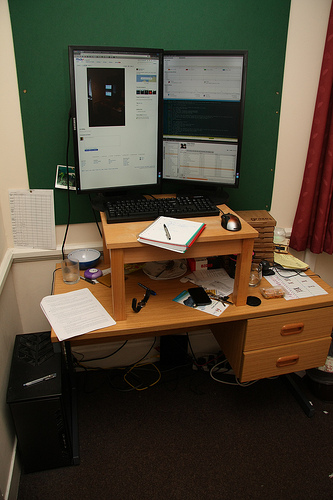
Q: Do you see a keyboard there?
A: Yes, there is a keyboard.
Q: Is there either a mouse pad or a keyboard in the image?
A: Yes, there is a keyboard.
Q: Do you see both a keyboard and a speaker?
A: No, there is a keyboard but no speakers.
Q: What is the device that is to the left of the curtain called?
A: The device is a keyboard.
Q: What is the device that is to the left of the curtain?
A: The device is a keyboard.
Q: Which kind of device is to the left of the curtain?
A: The device is a keyboard.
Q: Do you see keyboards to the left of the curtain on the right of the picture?
A: Yes, there is a keyboard to the left of the curtain.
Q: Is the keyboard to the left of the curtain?
A: Yes, the keyboard is to the left of the curtain.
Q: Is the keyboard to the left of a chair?
A: No, the keyboard is to the left of the curtain.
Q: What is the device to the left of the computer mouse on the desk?
A: The device is a keyboard.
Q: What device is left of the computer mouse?
A: The device is a keyboard.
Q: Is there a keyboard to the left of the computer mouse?
A: Yes, there is a keyboard to the left of the computer mouse.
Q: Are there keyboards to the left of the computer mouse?
A: Yes, there is a keyboard to the left of the computer mouse.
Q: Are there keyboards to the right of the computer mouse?
A: No, the keyboard is to the left of the computer mouse.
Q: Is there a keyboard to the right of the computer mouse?
A: No, the keyboard is to the left of the computer mouse.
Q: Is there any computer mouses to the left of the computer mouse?
A: No, there is a keyboard to the left of the computer mouse.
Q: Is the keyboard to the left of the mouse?
A: Yes, the keyboard is to the left of the mouse.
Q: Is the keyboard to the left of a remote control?
A: No, the keyboard is to the left of the mouse.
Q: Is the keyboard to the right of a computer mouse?
A: No, the keyboard is to the left of a computer mouse.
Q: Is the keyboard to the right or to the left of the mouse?
A: The keyboard is to the left of the mouse.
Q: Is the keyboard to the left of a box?
A: Yes, the keyboard is to the left of a box.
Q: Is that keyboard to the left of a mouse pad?
A: No, the keyboard is to the left of a box.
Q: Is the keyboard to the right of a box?
A: No, the keyboard is to the left of a box.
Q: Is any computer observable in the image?
A: Yes, there is a computer.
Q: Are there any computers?
A: Yes, there is a computer.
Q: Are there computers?
A: Yes, there is a computer.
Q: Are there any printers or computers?
A: Yes, there is a computer.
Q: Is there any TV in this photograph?
A: No, there are no televisions.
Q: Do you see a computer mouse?
A: Yes, there is a computer mouse.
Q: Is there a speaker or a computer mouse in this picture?
A: Yes, there is a computer mouse.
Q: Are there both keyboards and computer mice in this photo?
A: Yes, there are both a computer mouse and a keyboard.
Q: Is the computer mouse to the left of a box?
A: Yes, the computer mouse is to the left of a box.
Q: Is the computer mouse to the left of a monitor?
A: No, the computer mouse is to the left of a box.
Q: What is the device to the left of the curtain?
A: The device is a computer mouse.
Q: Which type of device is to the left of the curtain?
A: The device is a computer mouse.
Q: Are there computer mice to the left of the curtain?
A: Yes, there is a computer mouse to the left of the curtain.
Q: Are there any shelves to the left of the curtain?
A: No, there is a computer mouse to the left of the curtain.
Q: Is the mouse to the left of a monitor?
A: No, the mouse is to the left of the curtain.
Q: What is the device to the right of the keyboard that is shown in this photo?
A: The device is a computer mouse.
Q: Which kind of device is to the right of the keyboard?
A: The device is a computer mouse.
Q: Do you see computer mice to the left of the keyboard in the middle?
A: No, the computer mouse is to the right of the keyboard.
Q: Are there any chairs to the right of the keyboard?
A: No, there is a computer mouse to the right of the keyboard.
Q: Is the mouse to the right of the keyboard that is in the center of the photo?
A: Yes, the mouse is to the right of the keyboard.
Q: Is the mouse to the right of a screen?
A: No, the mouse is to the right of the keyboard.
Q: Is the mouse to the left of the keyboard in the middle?
A: No, the mouse is to the right of the keyboard.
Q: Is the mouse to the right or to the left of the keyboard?
A: The mouse is to the right of the keyboard.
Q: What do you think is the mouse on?
A: The mouse is on the desk.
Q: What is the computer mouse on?
A: The mouse is on the desk.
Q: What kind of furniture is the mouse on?
A: The mouse is on the desk.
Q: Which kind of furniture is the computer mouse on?
A: The mouse is on the desk.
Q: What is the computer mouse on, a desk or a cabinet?
A: The computer mouse is on a desk.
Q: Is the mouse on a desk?
A: Yes, the mouse is on a desk.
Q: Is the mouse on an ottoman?
A: No, the mouse is on a desk.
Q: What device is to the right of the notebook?
A: The device is a computer mouse.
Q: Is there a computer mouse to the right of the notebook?
A: Yes, there is a computer mouse to the right of the notebook.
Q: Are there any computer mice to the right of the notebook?
A: Yes, there is a computer mouse to the right of the notebook.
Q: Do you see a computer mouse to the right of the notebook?
A: Yes, there is a computer mouse to the right of the notebook.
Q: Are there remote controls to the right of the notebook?
A: No, there is a computer mouse to the right of the notebook.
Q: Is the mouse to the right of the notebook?
A: Yes, the mouse is to the right of the notebook.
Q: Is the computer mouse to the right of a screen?
A: No, the computer mouse is to the right of the notebook.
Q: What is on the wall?
A: The paper is on the wall.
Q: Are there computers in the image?
A: Yes, there is a computer.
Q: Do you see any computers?
A: Yes, there is a computer.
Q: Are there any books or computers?
A: Yes, there is a computer.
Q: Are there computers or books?
A: Yes, there is a computer.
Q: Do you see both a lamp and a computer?
A: No, there is a computer but no lamps.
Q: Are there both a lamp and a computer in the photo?
A: No, there is a computer but no lamps.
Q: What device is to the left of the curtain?
A: The device is a computer.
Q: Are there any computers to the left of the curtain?
A: Yes, there is a computer to the left of the curtain.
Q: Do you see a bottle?
A: No, there are no bottles.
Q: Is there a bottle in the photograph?
A: No, there are no bottles.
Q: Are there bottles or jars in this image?
A: No, there are no bottles or jars.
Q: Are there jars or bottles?
A: No, there are no bottles or jars.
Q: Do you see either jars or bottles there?
A: No, there are no bottles or jars.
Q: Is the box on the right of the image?
A: Yes, the box is on the right of the image.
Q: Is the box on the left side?
A: No, the box is on the right of the image.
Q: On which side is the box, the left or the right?
A: The box is on the right of the image.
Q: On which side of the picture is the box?
A: The box is on the right of the image.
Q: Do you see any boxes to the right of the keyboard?
A: Yes, there is a box to the right of the keyboard.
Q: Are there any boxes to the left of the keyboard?
A: No, the box is to the right of the keyboard.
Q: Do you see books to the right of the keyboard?
A: No, there is a box to the right of the keyboard.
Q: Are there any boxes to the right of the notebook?
A: Yes, there is a box to the right of the notebook.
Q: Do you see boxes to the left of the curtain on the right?
A: Yes, there is a box to the left of the curtain.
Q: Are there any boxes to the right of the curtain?
A: No, the box is to the left of the curtain.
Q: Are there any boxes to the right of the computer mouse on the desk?
A: Yes, there is a box to the right of the mouse.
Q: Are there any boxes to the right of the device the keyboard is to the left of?
A: Yes, there is a box to the right of the mouse.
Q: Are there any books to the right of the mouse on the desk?
A: No, there is a box to the right of the computer mouse.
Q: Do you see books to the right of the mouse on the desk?
A: No, there is a box to the right of the computer mouse.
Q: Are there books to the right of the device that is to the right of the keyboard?
A: No, there is a box to the right of the computer mouse.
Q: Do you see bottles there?
A: No, there are no bottles.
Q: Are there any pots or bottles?
A: No, there are no bottles or pots.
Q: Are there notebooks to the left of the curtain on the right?
A: Yes, there is a notebook to the left of the curtain.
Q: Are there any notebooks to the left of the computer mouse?
A: Yes, there is a notebook to the left of the computer mouse.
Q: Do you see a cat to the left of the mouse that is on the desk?
A: No, there is a notebook to the left of the mouse.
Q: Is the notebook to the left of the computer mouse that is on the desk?
A: Yes, the notebook is to the left of the computer mouse.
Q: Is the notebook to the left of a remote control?
A: No, the notebook is to the left of the computer mouse.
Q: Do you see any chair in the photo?
A: No, there are no chairs.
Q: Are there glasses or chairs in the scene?
A: No, there are no chairs or glasses.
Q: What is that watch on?
A: The watch is on the desk.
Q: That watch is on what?
A: The watch is on the desk.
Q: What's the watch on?
A: The watch is on the desk.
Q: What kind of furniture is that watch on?
A: The watch is on the desk.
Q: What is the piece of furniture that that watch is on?
A: The piece of furniture is a desk.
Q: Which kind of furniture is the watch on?
A: The watch is on the desk.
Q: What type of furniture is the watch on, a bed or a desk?
A: The watch is on a desk.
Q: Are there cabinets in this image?
A: No, there are no cabinets.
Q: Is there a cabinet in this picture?
A: No, there are no cabinets.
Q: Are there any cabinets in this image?
A: No, there are no cabinets.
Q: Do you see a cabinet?
A: No, there are no cabinets.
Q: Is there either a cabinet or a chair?
A: No, there are no cabinets or chairs.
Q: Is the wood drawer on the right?
A: Yes, the drawer is on the right of the image.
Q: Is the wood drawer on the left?
A: No, the drawer is on the right of the image.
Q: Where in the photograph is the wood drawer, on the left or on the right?
A: The drawer is on the right of the image.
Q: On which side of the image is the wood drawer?
A: The drawer is on the right of the image.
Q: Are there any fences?
A: No, there are no fences.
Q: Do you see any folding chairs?
A: No, there are no folding chairs.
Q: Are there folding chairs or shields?
A: No, there are no folding chairs or shields.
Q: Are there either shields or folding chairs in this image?
A: No, there are no folding chairs or shields.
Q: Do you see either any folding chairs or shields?
A: No, there are no folding chairs or shields.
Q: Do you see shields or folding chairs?
A: No, there are no folding chairs or shields.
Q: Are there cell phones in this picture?
A: Yes, there is a cell phone.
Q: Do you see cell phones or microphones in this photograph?
A: Yes, there is a cell phone.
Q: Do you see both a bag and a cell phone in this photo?
A: No, there is a cell phone but no bags.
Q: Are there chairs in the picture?
A: No, there are no chairs.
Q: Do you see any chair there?
A: No, there are no chairs.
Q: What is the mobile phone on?
A: The mobile phone is on the desk.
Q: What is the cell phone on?
A: The mobile phone is on the desk.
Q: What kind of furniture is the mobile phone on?
A: The mobile phone is on the desk.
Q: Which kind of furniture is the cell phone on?
A: The mobile phone is on the desk.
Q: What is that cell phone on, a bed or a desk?
A: The cell phone is on a desk.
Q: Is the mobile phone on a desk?
A: Yes, the mobile phone is on a desk.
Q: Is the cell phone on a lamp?
A: No, the cell phone is on a desk.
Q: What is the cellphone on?
A: The cellphone is on the desk.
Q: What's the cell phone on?
A: The cellphone is on the desk.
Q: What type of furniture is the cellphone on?
A: The cellphone is on the desk.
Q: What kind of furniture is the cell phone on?
A: The cellphone is on the desk.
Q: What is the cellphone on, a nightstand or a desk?
A: The cellphone is on a desk.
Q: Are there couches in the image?
A: No, there are no couches.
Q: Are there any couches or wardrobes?
A: No, there are no couches or wardrobes.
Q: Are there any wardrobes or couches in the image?
A: No, there are no couches or wardrobes.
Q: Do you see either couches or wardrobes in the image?
A: No, there are no couches or wardrobes.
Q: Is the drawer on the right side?
A: Yes, the drawer is on the right of the image.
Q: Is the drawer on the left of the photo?
A: No, the drawer is on the right of the image.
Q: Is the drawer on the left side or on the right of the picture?
A: The drawer is on the right of the image.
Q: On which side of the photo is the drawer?
A: The drawer is on the right of the image.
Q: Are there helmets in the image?
A: No, there are no helmets.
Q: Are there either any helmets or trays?
A: No, there are no helmets or trays.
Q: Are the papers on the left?
A: Yes, the papers are on the left of the image.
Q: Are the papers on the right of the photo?
A: No, the papers are on the left of the image.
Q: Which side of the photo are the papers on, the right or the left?
A: The papers are on the left of the image.